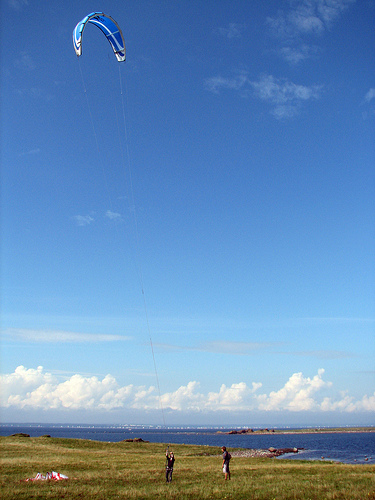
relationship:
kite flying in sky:
[70, 12, 128, 64] [4, 0, 374, 424]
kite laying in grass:
[25, 469, 65, 482] [1, 435, 371, 498]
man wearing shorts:
[218, 447, 231, 482] [220, 464, 230, 474]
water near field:
[1, 429, 373, 463] [139, 427, 374, 434]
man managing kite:
[163, 448, 174, 482] [70, 12, 128, 64]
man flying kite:
[161, 448, 175, 482] [70, 10, 127, 61]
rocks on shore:
[265, 444, 301, 456] [202, 446, 304, 456]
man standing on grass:
[218, 447, 231, 482] [1, 435, 371, 498]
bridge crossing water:
[31, 422, 170, 431] [1, 429, 373, 463]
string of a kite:
[77, 56, 171, 451] [70, 12, 128, 64]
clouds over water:
[1, 364, 373, 413] [1, 429, 373, 463]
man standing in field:
[218, 447, 231, 482] [26, 415, 360, 498]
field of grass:
[26, 415, 360, 498] [189, 473, 212, 492]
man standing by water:
[218, 447, 231, 482] [318, 436, 357, 458]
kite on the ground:
[25, 469, 65, 482] [89, 471, 106, 483]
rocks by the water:
[4, 430, 38, 440] [289, 430, 325, 444]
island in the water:
[221, 422, 363, 434] [166, 431, 204, 441]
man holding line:
[163, 448, 174, 482] [131, 244, 174, 438]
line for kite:
[131, 244, 174, 438] [61, 12, 126, 59]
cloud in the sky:
[241, 75, 298, 115] [108, 95, 154, 141]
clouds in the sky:
[26, 360, 332, 409] [138, 142, 189, 173]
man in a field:
[218, 447, 231, 482] [0, 428, 347, 498]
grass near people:
[273, 474, 327, 493] [157, 441, 236, 481]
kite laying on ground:
[25, 469, 65, 482] [98, 473, 127, 494]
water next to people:
[333, 438, 348, 455] [159, 436, 236, 483]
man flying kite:
[163, 448, 174, 482] [71, 14, 128, 59]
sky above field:
[174, 210, 227, 255] [6, 454, 367, 497]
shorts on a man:
[222, 462, 234, 482] [218, 447, 231, 482]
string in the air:
[138, 308, 167, 434] [57, 89, 251, 190]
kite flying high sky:
[77, 18, 128, 64] [196, 72, 221, 157]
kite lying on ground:
[70, 12, 128, 64] [77, 458, 112, 490]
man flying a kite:
[163, 448, 174, 482] [69, 14, 127, 54]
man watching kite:
[207, 429, 235, 476] [71, 15, 145, 68]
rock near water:
[111, 430, 149, 446] [164, 431, 213, 441]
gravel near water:
[229, 445, 269, 457] [28, 428, 362, 465]